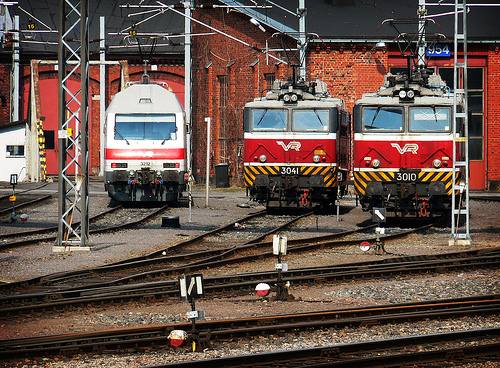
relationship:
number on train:
[275, 159, 325, 189] [234, 56, 349, 222]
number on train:
[275, 159, 306, 180] [234, 68, 355, 229]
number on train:
[275, 159, 306, 180] [232, 53, 343, 213]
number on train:
[390, 167, 419, 184] [345, 56, 485, 211]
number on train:
[390, 167, 424, 193] [340, 47, 484, 232]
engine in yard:
[354, 68, 454, 222] [20, 23, 485, 234]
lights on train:
[250, 139, 333, 181] [242, 50, 350, 221]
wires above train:
[108, 13, 170, 66] [100, 40, 200, 239]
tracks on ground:
[246, 216, 392, 361] [206, 213, 405, 346]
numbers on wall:
[416, 35, 465, 70] [364, 26, 470, 76]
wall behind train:
[322, 54, 417, 103] [264, 83, 484, 215]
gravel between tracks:
[235, 230, 445, 355] [338, 250, 452, 344]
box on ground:
[150, 211, 205, 246] [138, 201, 262, 281]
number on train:
[390, 167, 419, 184] [350, 53, 484, 238]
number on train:
[275, 159, 306, 180] [230, 41, 353, 237]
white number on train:
[394, 170, 417, 182] [343, 80, 461, 243]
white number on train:
[394, 170, 417, 182] [351, 60, 469, 233]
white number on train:
[405, 170, 413, 183] [351, 60, 469, 233]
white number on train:
[394, 170, 417, 182] [346, 60, 476, 240]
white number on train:
[278, 164, 301, 175] [245, 71, 350, 211]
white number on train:
[286, 161, 293, 174] [240, 77, 342, 207]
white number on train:
[278, 164, 301, 175] [245, 77, 349, 227]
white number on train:
[278, 164, 301, 175] [240, 77, 342, 207]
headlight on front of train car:
[258, 154, 268, 163] [232, 73, 342, 218]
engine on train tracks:
[229, 70, 356, 209] [8, 204, 334, 321]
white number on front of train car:
[278, 164, 301, 175] [245, 65, 345, 213]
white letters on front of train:
[270, 137, 304, 157] [245, 71, 350, 211]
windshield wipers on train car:
[248, 98, 329, 136] [240, 84, 346, 214]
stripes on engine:
[345, 164, 460, 204] [354, 68, 454, 222]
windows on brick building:
[398, 55, 478, 142] [264, 33, 496, 229]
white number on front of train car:
[394, 170, 417, 182] [351, 60, 473, 233]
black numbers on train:
[147, 153, 173, 176] [100, 68, 193, 202]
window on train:
[245, 105, 291, 135] [242, 73, 345, 214]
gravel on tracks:
[235, 230, 445, 355] [179, 242, 489, 359]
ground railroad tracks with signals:
[0, 213, 500, 368] [187, 235, 324, 346]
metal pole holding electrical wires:
[43, 50, 103, 284] [112, 99, 205, 103]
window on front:
[113, 119, 148, 143] [100, 83, 186, 186]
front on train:
[100, 83, 186, 186] [99, 75, 198, 212]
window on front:
[138, 113, 178, 146] [100, 83, 186, 186]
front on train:
[100, 83, 186, 186] [104, 76, 188, 206]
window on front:
[245, 105, 291, 135] [241, 99, 347, 194]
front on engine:
[241, 99, 347, 194] [229, 70, 356, 209]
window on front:
[291, 106, 329, 140] [241, 99, 347, 194]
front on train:
[241, 99, 347, 194] [238, 69, 345, 206]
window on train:
[245, 105, 291, 135] [221, 63, 347, 226]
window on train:
[291, 106, 329, 140] [226, 70, 354, 254]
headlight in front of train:
[239, 136, 339, 179] [235, 72, 341, 231]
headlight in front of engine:
[354, 143, 477, 185] [354, 68, 454, 222]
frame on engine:
[224, 144, 337, 176] [215, 70, 356, 245]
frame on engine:
[354, 156, 473, 213] [344, 62, 466, 240]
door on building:
[16, 52, 180, 181] [23, 28, 354, 293]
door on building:
[16, 52, 180, 181] [14, 23, 404, 202]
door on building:
[289, 39, 406, 212] [33, 20, 459, 262]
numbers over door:
[60, 80, 91, 178] [38, 45, 166, 249]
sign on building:
[407, 28, 464, 73] [20, 13, 470, 281]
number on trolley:
[390, 167, 419, 184] [332, 93, 470, 258]